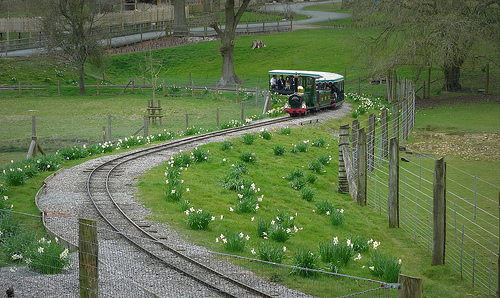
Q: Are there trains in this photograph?
A: Yes, there is a train.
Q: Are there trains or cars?
A: Yes, there is a train.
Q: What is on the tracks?
A: The train is on the tracks.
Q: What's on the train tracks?
A: The train is on the tracks.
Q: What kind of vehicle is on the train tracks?
A: The vehicle is a train.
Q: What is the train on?
A: The train is on the railroad tracks.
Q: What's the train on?
A: The train is on the railroad tracks.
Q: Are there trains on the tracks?
A: Yes, there is a train on the tracks.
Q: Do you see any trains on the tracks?
A: Yes, there is a train on the tracks.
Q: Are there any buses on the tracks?
A: No, there is a train on the tracks.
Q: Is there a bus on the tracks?
A: No, there is a train on the tracks.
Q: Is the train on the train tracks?
A: Yes, the train is on the train tracks.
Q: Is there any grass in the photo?
A: Yes, there is grass.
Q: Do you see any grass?
A: Yes, there is grass.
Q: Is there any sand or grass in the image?
A: Yes, there is grass.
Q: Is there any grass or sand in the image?
A: Yes, there is grass.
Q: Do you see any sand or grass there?
A: Yes, there is grass.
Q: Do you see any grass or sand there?
A: Yes, there is grass.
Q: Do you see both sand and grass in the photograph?
A: No, there is grass but no sand.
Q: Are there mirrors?
A: No, there are no mirrors.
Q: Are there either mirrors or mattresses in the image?
A: No, there are no mirrors or mattresses.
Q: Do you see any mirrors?
A: No, there are no mirrors.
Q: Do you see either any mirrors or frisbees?
A: No, there are no mirrors or frisbees.